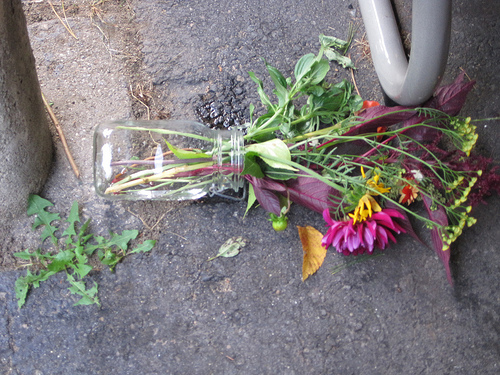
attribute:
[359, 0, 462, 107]
leg — bent, metal, white, support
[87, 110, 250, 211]
jar — clear, glass, lying, used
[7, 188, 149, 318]
dandelion — growing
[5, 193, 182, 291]
crack — weird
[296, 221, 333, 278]
leaf — yellow, yellowed, dried, small, by itself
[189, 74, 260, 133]
water — spilled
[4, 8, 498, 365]
ground — paved, gray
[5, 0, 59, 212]
post — concrete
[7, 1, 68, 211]
base — concrete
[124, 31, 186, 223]
grass — dead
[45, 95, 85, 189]
twig — brown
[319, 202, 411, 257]
flower — pink, resembling, purple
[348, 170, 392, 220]
black eyed susan — young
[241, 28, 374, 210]
leaves — green, mixed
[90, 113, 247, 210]
mason jar — glass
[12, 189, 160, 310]
plant — green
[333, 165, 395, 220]
flowers — yellow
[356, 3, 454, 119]
bar — handle, white, metal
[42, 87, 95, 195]
stick — brown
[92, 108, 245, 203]
vase — jar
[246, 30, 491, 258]
bunch — flowers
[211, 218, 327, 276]
stuff — cool, leafy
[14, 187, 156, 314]
weed — growing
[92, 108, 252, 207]
glass — spilled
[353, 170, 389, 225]
flower — yellow, dried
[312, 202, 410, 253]
petals — pink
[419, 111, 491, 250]
flowers — yellow, tiny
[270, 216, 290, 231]
berry — green, small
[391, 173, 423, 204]
flower — dying, orange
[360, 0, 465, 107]
piece — metal, curved, bike rack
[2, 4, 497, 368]
surface — pitted